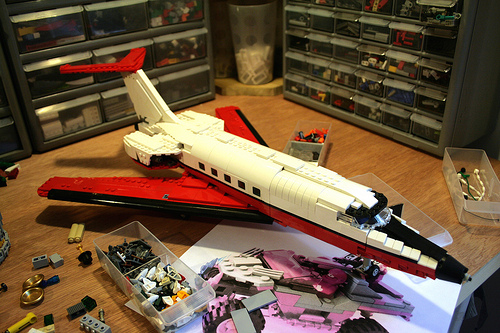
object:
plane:
[0, 0, 500, 333]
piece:
[66, 223, 86, 243]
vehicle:
[196, 247, 412, 333]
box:
[439, 147, 499, 226]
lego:
[295, 127, 328, 144]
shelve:
[281, 0, 500, 157]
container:
[282, 120, 334, 168]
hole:
[78, 314, 112, 333]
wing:
[36, 175, 273, 226]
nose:
[374, 193, 472, 285]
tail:
[59, 48, 177, 123]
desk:
[0, 95, 500, 333]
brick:
[99, 307, 105, 323]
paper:
[120, 225, 462, 333]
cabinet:
[0, 0, 217, 165]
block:
[143, 281, 157, 292]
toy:
[36, 47, 472, 286]